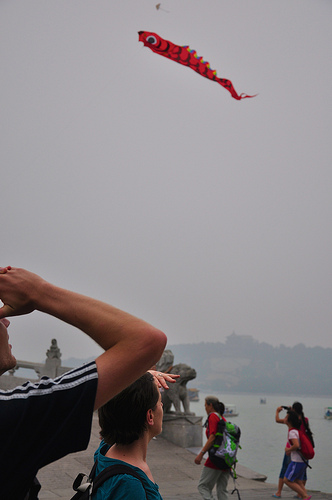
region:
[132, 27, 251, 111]
a long red kite in the sky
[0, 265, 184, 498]
a couple of people looking at the kite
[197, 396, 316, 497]
people walking along the street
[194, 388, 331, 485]
the ocean behind the people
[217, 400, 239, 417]
a small boat in the water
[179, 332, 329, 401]
a hill behind the ocean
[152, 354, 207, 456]
a statue on the plaza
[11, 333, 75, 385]
a wall next to the people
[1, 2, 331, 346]
the cloudy sky above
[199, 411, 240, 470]
a colorful backpack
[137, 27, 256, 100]
the kite is in the sky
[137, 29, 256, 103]
the kite is a dragon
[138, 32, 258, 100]
the kite is black and red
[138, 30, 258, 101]
the kite has an eye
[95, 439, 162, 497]
the woman has a blue shirt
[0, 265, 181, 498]
the people look up at the sky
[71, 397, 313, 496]
the people wear back packs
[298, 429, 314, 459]
the child has a red back pack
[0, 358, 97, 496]
the man has a striped shirt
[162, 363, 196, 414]
the sculpture is of an animal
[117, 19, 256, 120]
Red kite is in the sky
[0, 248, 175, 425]
Man looking up at kite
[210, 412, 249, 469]
Persons backpack is green,black and white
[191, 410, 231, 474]
Person is wearing a red shirt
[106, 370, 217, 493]
Woman looking up in the sky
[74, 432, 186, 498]
Woman is wearing a dark teal shirt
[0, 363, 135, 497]
Man is wearing a black shirt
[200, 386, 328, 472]
Body of water is in the background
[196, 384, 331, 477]
Group of people are in the background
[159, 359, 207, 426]
A animal made of stone is in background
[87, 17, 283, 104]
a kite in the sky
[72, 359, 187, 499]
a person shielding his eyes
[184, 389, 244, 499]
woman with a baby on her back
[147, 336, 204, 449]
a statue by the water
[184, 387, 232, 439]
woman with a pony tail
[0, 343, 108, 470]
stripes on a short sleeve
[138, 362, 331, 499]
people near a body of water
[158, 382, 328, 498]
water with boats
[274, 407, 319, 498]
a youngster with a back pack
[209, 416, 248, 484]
a baby dressed in green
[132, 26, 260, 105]
fish kite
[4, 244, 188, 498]
two people looking at a kite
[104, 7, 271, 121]
a large kite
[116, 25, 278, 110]
a red kite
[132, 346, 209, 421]
a stone lion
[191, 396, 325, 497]
four people walking by the water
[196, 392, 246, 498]
the man's green backpack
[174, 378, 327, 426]
four boats in the water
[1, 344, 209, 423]
stone railing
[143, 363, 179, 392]
a ring on the woman's hand